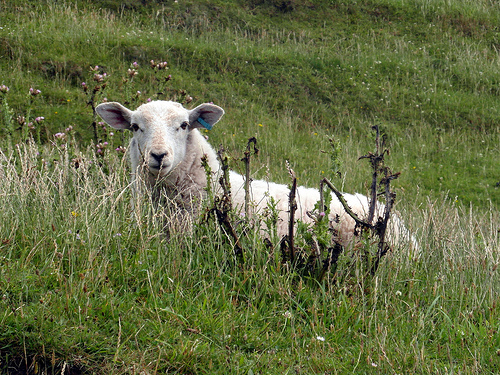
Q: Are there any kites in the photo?
A: No, there are no kites.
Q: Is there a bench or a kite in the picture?
A: No, there are no kites or benches.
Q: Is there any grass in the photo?
A: Yes, there is grass.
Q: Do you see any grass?
A: Yes, there is grass.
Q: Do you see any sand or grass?
A: Yes, there is grass.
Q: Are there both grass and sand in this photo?
A: No, there is grass but no sand.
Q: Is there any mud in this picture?
A: No, there is no mud.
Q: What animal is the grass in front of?
A: The grass is in front of the sheep.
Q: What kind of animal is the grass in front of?
A: The grass is in front of the sheep.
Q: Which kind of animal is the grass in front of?
A: The grass is in front of the sheep.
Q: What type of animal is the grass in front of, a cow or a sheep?
A: The grass is in front of a sheep.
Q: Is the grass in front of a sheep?
A: Yes, the grass is in front of a sheep.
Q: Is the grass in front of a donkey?
A: No, the grass is in front of a sheep.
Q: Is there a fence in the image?
A: No, there are no fences.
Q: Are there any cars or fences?
A: No, there are no fences or cars.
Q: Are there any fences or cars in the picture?
A: No, there are no fences or cars.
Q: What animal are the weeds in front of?
A: The weeds are in front of the sheep.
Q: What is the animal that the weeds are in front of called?
A: The animal is a sheep.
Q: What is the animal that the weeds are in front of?
A: The animal is a sheep.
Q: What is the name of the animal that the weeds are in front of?
A: The animal is a sheep.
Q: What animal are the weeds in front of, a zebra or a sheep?
A: The weeds are in front of a sheep.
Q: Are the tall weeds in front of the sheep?
A: Yes, the weeds are in front of the sheep.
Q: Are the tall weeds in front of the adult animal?
A: Yes, the weeds are in front of the sheep.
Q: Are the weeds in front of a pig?
A: No, the weeds are in front of the sheep.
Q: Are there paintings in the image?
A: No, there are no paintings.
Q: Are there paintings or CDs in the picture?
A: No, there are no paintings or cds.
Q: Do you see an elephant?
A: No, there are no elephants.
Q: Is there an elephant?
A: No, there are no elephants.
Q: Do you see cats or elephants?
A: No, there are no elephants or cats.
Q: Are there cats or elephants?
A: No, there are no elephants or cats.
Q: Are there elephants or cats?
A: No, there are no elephants or cats.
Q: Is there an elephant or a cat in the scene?
A: No, there are no elephants or cats.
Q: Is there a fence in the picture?
A: No, there are no fences.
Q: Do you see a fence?
A: No, there are no fences.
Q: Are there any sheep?
A: Yes, there is a sheep.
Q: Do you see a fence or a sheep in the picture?
A: Yes, there is a sheep.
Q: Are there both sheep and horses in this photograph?
A: No, there is a sheep but no horses.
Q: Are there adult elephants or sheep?
A: Yes, there is an adult sheep.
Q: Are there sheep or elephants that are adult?
A: Yes, the sheep is adult.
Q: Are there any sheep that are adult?
A: Yes, there is a sheep that is adult.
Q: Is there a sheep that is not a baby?
A: Yes, there is a adult sheep.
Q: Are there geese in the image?
A: No, there are no geese.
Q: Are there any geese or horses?
A: No, there are no geese or horses.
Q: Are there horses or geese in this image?
A: No, there are no geese or horses.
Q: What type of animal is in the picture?
A: The animal is a sheep.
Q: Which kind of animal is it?
A: The animal is a sheep.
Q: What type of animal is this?
A: This is a sheep.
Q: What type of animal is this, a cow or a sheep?
A: This is a sheep.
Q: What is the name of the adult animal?
A: The animal is a sheep.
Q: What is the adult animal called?
A: The animal is a sheep.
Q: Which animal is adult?
A: The animal is a sheep.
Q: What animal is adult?
A: The animal is a sheep.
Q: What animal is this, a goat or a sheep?
A: This is a sheep.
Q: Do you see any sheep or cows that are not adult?
A: No, there is a sheep but it is adult.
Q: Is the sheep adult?
A: Yes, the sheep is adult.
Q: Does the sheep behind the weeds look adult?
A: Yes, the sheep is adult.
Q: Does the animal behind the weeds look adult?
A: Yes, the sheep is adult.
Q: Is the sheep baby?
A: No, the sheep is adult.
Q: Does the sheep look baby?
A: No, the sheep is adult.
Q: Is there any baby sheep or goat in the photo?
A: No, there is a sheep but it is adult.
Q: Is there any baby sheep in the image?
A: No, there is a sheep but it is adult.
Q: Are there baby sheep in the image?
A: No, there is a sheep but it is adult.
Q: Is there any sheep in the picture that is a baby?
A: No, there is a sheep but it is adult.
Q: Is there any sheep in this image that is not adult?
A: No, there is a sheep but it is adult.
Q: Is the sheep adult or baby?
A: The sheep is adult.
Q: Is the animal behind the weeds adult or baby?
A: The sheep is adult.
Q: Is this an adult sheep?
A: Yes, this is an adult sheep.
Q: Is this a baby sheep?
A: No, this is an adult sheep.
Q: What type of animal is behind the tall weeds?
A: The animal is a sheep.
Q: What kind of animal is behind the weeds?
A: The animal is a sheep.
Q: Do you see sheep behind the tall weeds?
A: Yes, there is a sheep behind the weeds.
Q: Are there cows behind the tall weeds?
A: No, there is a sheep behind the weeds.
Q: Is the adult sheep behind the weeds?
A: Yes, the sheep is behind the weeds.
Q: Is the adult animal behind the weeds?
A: Yes, the sheep is behind the weeds.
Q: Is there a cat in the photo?
A: No, there are no cats.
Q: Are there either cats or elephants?
A: No, there are no cats or elephants.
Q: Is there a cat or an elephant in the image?
A: No, there are no cats or elephants.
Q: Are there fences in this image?
A: No, there are no fences.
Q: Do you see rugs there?
A: No, there are no rugs.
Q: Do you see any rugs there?
A: No, there are no rugs.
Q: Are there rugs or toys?
A: No, there are no rugs or toys.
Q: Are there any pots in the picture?
A: No, there are no pots.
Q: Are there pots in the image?
A: No, there are no pots.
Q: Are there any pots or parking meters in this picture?
A: No, there are no pots or parking meters.